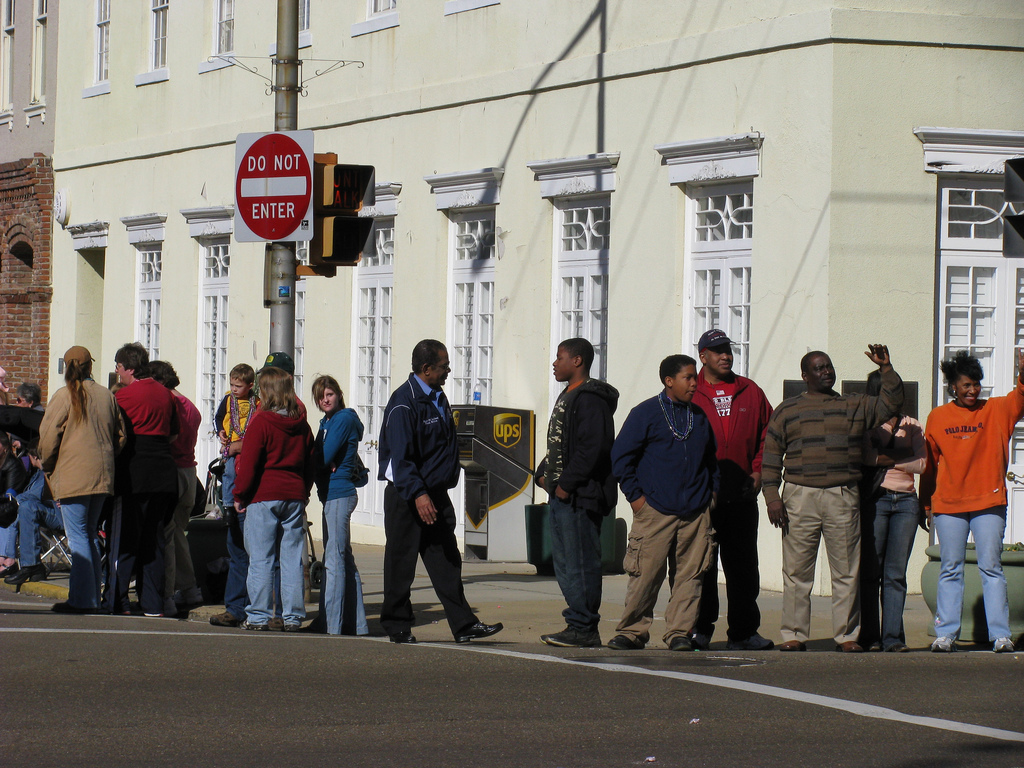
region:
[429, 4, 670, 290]
shadow of a post on the wall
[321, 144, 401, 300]
cross walk signal light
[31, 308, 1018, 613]
People on the sidewalk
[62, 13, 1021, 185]
White building in the background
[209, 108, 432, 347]
A Do Not Enter sign is on a light post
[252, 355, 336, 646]
A woman is wearing blue jeans and a red coat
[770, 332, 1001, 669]
Two people are waving their arms in the air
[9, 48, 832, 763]
It is a bright and sunny day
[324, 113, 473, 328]
The electronic crosswalk sign is lit do not walk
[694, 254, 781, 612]
An older man is wearing a red jacket with a black hat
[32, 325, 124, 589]
A woman is wearing blue jeans, a brown jacket and a brown hat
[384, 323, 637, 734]
Two men are turned towards each other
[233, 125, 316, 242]
Do Not Enter road sign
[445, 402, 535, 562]
UPS self serve mailbox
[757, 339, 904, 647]
man in slacks and brown sweater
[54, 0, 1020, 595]
light yellow building with white window frames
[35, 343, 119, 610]
person in brown jacket with ponytail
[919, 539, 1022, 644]
large green decorative pot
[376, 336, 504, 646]
man crossing the road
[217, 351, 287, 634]
man holding a child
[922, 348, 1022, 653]
woman in orange sweater and jeans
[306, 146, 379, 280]
street crossing light signal box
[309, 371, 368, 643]
woman looking back over her left shoulder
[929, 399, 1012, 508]
woman wearing orange shirt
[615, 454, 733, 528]
person with hands in pockets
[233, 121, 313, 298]
red and white sign on pole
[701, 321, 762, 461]
man wearing red jacket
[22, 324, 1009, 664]
several people standing near a curb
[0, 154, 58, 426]
a partially visible brick building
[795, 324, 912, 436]
man with his left arm raised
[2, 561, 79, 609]
yellow paint on a curb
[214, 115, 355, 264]
red and white street sign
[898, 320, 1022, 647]
woman in orange sweatshirt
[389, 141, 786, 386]
windows on building wall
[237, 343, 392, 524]
women in sweat shirts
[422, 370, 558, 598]
ups mail drop box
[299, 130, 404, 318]
old yellow street light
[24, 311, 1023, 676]
people waiting in line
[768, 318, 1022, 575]
three people waving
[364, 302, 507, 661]
man in black pants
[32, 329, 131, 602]
tall person with ponytail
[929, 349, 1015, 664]
A lady wearing an orange sweater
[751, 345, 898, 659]
Man wearing black and brown sweater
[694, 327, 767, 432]
Man wearing red shirt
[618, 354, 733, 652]
Someone wearing a necklace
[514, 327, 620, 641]
Boy wearing hooded jacket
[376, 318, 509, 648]
Man wearing shiny shoes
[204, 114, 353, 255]
Red and white street sign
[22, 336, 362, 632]
People standing in line waiting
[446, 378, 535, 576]
package carrier box on sidewalk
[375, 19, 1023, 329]
Yellow building with white windows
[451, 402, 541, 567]
UPS drop box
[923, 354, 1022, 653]
woman wearing orange sweatshirt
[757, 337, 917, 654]
man waving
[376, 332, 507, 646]
man wearing a blue jacket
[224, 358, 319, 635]
woman wearing a red jacket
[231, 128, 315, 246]
a do not enter sign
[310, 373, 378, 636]
a woman looking back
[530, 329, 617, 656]
young man in a dark jacket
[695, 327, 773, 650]
man wearing a hat